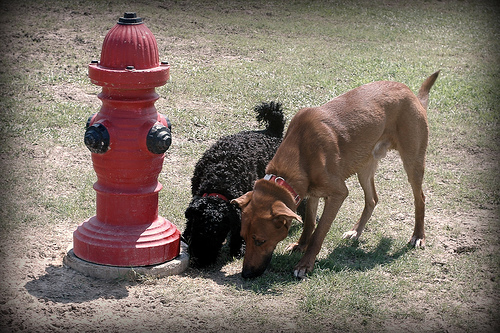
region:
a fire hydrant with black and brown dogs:
[61, 6, 461, 302]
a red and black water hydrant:
[65, 5, 195, 290]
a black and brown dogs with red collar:
[181, 50, 461, 305]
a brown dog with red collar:
[231, 55, 452, 292]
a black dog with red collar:
[183, 92, 277, 272]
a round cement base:
[51, 250, 193, 290]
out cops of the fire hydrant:
[71, 112, 182, 162]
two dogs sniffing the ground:
[182, 62, 476, 305]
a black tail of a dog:
[248, 95, 285, 136]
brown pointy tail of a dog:
[414, 65, 451, 117]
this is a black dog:
[172, 70, 304, 265]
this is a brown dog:
[213, 71, 456, 293]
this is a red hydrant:
[63, 5, 203, 280]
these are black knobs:
[75, 106, 194, 155]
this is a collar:
[256, 156, 315, 216]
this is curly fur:
[215, 143, 242, 171]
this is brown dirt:
[145, 294, 200, 316]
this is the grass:
[472, 169, 494, 199]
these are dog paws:
[278, 222, 443, 287]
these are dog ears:
[237, 195, 304, 231]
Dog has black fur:
[206, 142, 251, 169]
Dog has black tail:
[271, 95, 284, 132]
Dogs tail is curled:
[249, 96, 286, 132]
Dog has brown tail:
[421, 66, 433, 104]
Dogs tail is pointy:
[413, 65, 447, 100]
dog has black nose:
[231, 264, 261, 281]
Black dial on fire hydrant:
[71, 124, 120, 158]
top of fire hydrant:
[87, 13, 169, 75]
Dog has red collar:
[188, 192, 240, 202]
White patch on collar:
[263, 170, 275, 182]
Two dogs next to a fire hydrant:
[51, 9, 461, 312]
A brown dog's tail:
[411, 65, 441, 115]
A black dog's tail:
[250, 95, 295, 138]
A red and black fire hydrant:
[60, 4, 192, 286]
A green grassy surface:
[302, 15, 450, 67]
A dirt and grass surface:
[51, 280, 258, 321]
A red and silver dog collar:
[260, 167, 302, 210]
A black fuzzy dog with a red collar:
[180, 90, 238, 269]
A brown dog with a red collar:
[230, 71, 454, 282]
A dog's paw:
[399, 210, 432, 258]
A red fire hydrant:
[61, 4, 186, 277]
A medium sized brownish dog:
[243, 61, 458, 278]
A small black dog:
[183, 103, 283, 268]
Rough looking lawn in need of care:
[254, 18, 426, 64]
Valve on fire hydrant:
[77, 124, 119, 156]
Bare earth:
[46, 289, 198, 322]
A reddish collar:
[260, 165, 318, 210]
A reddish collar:
[193, 187, 233, 213]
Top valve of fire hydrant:
[108, 7, 156, 35]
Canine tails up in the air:
[248, 65, 487, 145]